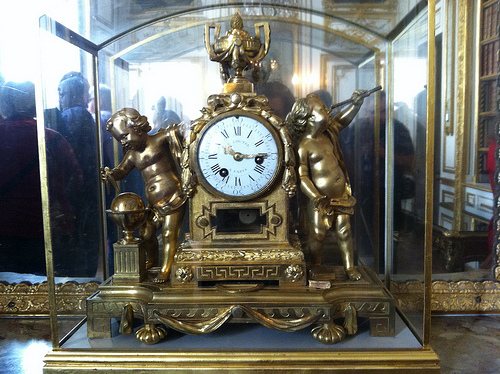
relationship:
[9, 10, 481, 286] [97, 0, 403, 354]
mirror behind clock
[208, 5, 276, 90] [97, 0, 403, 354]
trophy decorating clock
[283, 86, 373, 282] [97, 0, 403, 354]
children part of clock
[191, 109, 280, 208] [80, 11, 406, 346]
clock on statue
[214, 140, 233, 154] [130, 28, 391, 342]
hand on clock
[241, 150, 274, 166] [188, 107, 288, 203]
hand on clock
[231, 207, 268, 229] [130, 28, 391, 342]
bell inside clock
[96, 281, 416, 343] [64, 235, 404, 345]
bottom of stand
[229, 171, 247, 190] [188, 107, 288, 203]
six on clock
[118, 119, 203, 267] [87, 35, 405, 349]
children of clock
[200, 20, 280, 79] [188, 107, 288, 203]
carving on clock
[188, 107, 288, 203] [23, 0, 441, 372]
clock inside case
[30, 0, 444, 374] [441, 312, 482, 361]
case on table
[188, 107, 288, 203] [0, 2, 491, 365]
clock in museum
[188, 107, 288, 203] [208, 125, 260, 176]
clock uses numerals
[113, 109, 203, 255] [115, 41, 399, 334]
children on clock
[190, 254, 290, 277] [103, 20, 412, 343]
design on clock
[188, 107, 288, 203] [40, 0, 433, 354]
clock in case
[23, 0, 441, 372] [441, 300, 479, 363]
case on table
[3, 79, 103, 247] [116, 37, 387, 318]
people looking at clock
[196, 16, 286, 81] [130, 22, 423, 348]
statue on clock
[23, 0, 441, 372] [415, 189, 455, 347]
case has frame